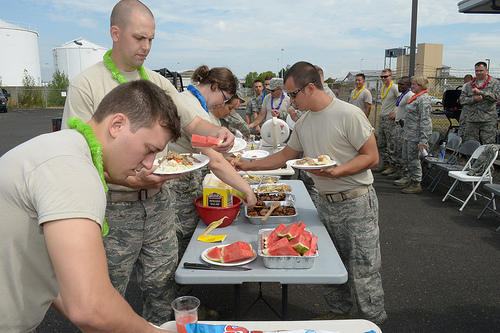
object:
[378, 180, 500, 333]
pavement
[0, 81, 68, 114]
fence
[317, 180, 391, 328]
pants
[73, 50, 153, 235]
leis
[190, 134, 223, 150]
slice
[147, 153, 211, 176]
plate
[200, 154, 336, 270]
food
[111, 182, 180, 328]
fatigues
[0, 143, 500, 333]
table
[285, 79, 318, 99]
sunglasses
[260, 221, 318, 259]
slices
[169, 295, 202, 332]
juice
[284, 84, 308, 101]
shades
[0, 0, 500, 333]
personnel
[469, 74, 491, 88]
lei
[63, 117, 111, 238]
flowers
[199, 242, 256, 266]
plate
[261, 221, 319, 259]
watermelon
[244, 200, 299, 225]
tray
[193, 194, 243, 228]
bowl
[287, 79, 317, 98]
glasses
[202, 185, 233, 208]
box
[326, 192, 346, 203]
buckle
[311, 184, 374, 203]
belt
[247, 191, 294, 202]
pan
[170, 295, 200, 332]
cup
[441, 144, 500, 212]
chairs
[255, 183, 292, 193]
chips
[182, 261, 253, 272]
knife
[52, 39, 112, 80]
tank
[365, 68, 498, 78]
wire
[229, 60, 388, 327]
man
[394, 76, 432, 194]
men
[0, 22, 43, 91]
silos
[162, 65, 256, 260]
woman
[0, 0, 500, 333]
members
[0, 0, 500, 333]
troops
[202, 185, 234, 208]
condiment